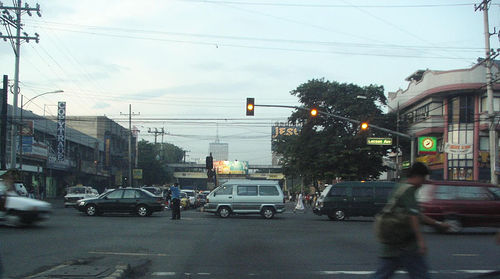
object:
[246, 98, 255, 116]
light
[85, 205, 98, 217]
wheel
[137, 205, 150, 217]
wheel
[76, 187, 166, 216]
vehicle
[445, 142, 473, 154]
banner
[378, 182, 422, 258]
shirt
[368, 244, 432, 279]
pants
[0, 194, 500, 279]
road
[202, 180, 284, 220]
car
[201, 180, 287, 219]
van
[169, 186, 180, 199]
shirt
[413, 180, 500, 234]
car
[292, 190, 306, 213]
man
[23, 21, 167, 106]
electrical wires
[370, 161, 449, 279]
guy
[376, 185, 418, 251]
backpack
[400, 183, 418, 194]
shoulder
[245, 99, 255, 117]
traffic signal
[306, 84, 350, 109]
leaves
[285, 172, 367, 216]
roadside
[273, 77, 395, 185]
tree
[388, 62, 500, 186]
building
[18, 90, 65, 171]
streetlamp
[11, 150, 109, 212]
roadside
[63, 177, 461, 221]
traffic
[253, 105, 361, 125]
pole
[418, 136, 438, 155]
sign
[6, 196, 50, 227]
car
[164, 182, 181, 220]
man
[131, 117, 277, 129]
power line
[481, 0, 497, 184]
power rod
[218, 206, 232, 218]
front tire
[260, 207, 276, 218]
rear tire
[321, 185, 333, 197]
windshield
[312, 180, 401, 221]
vehicle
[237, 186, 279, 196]
windows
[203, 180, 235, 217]
front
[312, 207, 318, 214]
vehicles bumper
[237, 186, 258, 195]
side window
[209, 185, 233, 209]
door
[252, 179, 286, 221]
rear part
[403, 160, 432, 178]
hat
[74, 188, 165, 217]
car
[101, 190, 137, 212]
doors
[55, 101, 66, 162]
sign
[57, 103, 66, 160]
letters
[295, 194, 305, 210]
dress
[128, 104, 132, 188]
pole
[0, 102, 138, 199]
building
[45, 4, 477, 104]
clouds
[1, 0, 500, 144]
sky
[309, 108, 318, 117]
light